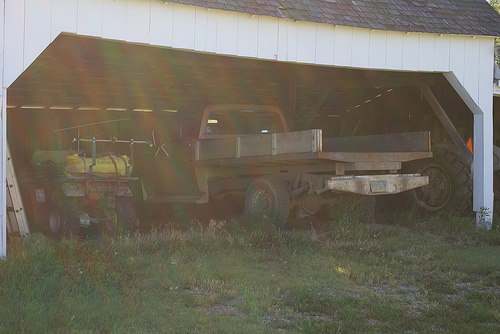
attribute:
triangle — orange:
[451, 124, 485, 167]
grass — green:
[64, 265, 239, 327]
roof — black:
[145, 1, 497, 40]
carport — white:
[3, 1, 495, 257]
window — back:
[206, 109, 281, 136]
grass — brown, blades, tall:
[9, 227, 497, 332]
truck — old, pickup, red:
[139, 103, 439, 230]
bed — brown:
[197, 132, 439, 163]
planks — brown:
[46, 7, 477, 77]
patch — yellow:
[330, 262, 353, 279]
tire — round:
[244, 177, 293, 227]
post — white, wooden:
[467, 109, 494, 233]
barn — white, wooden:
[0, 0, 497, 231]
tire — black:
[221, 150, 297, 244]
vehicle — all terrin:
[155, 96, 438, 223]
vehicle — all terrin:
[18, 136, 166, 236]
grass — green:
[2, 217, 498, 332]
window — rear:
[203, 107, 288, 133]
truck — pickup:
[132, 109, 437, 218]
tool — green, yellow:
[44, 137, 151, 229]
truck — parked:
[152, 94, 473, 255]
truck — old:
[141, 62, 446, 251]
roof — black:
[206, 0, 499, 42]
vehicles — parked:
[22, 96, 449, 233]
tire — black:
[240, 174, 288, 227]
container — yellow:
[61, 146, 141, 177]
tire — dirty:
[238, 169, 296, 231]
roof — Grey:
[306, 1, 495, 80]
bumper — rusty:
[312, 170, 442, 197]